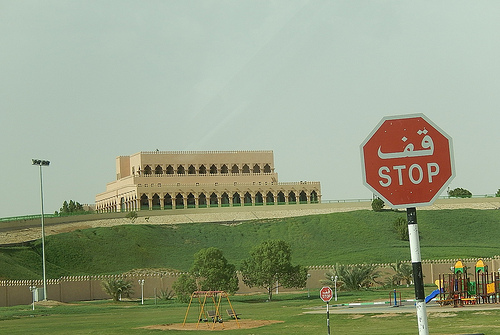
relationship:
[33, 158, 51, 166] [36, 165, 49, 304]
light on pole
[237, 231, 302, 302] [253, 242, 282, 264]
tree with leaves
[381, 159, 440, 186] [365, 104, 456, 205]
letters on stop sign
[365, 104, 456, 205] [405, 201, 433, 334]
stop sign on pole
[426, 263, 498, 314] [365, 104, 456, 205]
playground equipment behind stop sign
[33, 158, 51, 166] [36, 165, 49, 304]
light on top of pole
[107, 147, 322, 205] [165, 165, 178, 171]
building with window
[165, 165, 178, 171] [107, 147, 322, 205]
window on building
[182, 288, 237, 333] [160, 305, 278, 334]
swing set on a patch of dirt